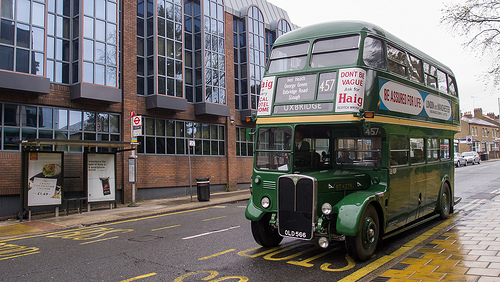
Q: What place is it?
A: It is a street.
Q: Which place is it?
A: It is a street.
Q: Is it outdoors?
A: Yes, it is outdoors.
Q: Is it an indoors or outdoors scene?
A: It is outdoors.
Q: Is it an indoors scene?
A: No, it is outdoors.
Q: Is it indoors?
A: No, it is outdoors.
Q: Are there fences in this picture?
A: No, there are no fences.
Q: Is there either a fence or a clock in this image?
A: No, there are no fences or clocks.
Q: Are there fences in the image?
A: No, there are no fences.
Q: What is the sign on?
A: The sign is on the pole.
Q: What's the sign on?
A: The sign is on the pole.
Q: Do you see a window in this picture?
A: Yes, there is a window.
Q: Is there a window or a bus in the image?
A: Yes, there is a window.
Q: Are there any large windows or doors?
A: Yes, there is a large window.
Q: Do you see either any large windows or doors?
A: Yes, there is a large window.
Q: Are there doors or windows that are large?
A: Yes, the window is large.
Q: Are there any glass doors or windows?
A: Yes, there is a glass window.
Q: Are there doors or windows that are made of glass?
A: Yes, the window is made of glass.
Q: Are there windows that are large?
A: Yes, there is a large window.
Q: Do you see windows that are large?
A: Yes, there is a window that is large.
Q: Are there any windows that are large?
A: Yes, there is a window that is large.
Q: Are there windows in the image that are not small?
A: Yes, there is a large window.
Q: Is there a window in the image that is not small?
A: Yes, there is a large window.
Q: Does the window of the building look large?
A: Yes, the window is large.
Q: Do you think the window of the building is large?
A: Yes, the window is large.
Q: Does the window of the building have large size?
A: Yes, the window is large.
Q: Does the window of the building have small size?
A: No, the window is large.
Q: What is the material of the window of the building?
A: The window is made of glass.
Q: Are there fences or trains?
A: No, there are no fences or trains.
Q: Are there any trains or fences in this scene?
A: No, there are no fences or trains.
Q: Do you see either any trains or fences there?
A: No, there are no fences or trains.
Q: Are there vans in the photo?
A: No, there are no vans.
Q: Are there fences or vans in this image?
A: No, there are no vans or fences.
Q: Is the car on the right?
A: Yes, the car is on the right of the image.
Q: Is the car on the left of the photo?
A: No, the car is on the right of the image.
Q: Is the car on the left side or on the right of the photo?
A: The car is on the right of the image.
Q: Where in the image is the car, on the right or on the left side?
A: The car is on the right of the image.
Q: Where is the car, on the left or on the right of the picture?
A: The car is on the right of the image.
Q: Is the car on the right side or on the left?
A: The car is on the right of the image.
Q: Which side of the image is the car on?
A: The car is on the right of the image.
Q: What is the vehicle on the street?
A: The vehicle is a car.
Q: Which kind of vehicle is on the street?
A: The vehicle is a car.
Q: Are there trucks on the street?
A: No, there is a car on the street.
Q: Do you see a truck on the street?
A: No, there is a car on the street.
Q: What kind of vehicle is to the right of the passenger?
A: The vehicle is a car.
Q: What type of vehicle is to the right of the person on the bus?
A: The vehicle is a car.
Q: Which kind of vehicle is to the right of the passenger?
A: The vehicle is a car.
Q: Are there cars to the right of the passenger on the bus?
A: Yes, there is a car to the right of the passenger.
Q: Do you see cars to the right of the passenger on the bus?
A: Yes, there is a car to the right of the passenger.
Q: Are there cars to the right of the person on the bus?
A: Yes, there is a car to the right of the passenger.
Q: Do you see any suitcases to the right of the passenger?
A: No, there is a car to the right of the passenger.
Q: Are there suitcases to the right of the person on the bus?
A: No, there is a car to the right of the passenger.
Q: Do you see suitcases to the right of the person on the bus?
A: No, there is a car to the right of the passenger.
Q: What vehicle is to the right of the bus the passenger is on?
A: The vehicle is a car.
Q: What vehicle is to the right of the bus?
A: The vehicle is a car.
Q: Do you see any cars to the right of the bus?
A: Yes, there is a car to the right of the bus.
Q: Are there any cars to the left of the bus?
A: No, the car is to the right of the bus.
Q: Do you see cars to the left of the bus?
A: No, the car is to the right of the bus.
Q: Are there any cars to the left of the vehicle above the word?
A: No, the car is to the right of the bus.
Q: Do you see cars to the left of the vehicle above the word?
A: No, the car is to the right of the bus.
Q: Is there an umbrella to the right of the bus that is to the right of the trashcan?
A: No, there is a car to the right of the bus.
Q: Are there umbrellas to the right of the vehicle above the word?
A: No, there is a car to the right of the bus.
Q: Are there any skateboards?
A: No, there are no skateboards.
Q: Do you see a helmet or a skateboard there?
A: No, there are no skateboards or helmets.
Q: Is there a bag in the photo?
A: No, there are no bags.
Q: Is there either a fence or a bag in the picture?
A: No, there are no bags or fences.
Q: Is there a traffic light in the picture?
A: No, there are no traffic lights.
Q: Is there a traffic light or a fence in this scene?
A: No, there are no traffic lights or fences.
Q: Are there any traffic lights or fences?
A: No, there are no traffic lights or fences.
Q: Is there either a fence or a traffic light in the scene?
A: No, there are no traffic lights or fences.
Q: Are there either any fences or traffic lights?
A: No, there are no traffic lights or fences.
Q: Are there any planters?
A: No, there are no planters.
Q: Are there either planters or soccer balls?
A: No, there are no planters or soccer balls.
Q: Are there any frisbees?
A: No, there are no frisbees.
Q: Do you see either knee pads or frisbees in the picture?
A: No, there are no frisbees or knee pads.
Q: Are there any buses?
A: Yes, there is a bus.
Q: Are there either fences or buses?
A: Yes, there is a bus.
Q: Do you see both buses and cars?
A: Yes, there are both a bus and a car.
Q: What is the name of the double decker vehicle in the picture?
A: The vehicle is a bus.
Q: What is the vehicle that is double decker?
A: The vehicle is a bus.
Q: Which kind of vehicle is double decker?
A: The vehicle is a bus.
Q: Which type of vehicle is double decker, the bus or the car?
A: The bus is double decker.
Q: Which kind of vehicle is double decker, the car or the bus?
A: The bus is double decker.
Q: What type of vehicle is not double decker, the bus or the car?
A: The car is not double decker.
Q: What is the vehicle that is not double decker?
A: The vehicle is a car.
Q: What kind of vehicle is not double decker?
A: The vehicle is a car.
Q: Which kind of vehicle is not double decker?
A: The vehicle is a car.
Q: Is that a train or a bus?
A: That is a bus.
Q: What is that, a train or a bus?
A: That is a bus.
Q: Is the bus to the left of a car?
A: Yes, the bus is to the left of a car.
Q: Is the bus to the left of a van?
A: No, the bus is to the left of a car.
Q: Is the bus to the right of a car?
A: No, the bus is to the left of a car.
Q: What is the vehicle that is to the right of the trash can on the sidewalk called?
A: The vehicle is a bus.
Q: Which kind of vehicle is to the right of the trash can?
A: The vehicle is a bus.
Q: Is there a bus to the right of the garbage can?
A: Yes, there is a bus to the right of the garbage can.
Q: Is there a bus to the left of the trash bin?
A: No, the bus is to the right of the trash bin.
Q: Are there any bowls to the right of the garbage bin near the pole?
A: No, there is a bus to the right of the trash bin.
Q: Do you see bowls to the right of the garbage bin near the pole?
A: No, there is a bus to the right of the trash bin.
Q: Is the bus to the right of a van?
A: No, the bus is to the right of the garbage can.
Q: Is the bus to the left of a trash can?
A: No, the bus is to the right of a trash can.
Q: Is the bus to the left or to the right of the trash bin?
A: The bus is to the right of the trash bin.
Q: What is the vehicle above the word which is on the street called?
A: The vehicle is a bus.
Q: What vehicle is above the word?
A: The vehicle is a bus.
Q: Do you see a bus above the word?
A: Yes, there is a bus above the word.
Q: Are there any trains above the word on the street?
A: No, there is a bus above the word.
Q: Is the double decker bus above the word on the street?
A: Yes, the bus is above the word.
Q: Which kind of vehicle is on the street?
A: The vehicle is a bus.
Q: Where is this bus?
A: The bus is on the street.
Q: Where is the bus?
A: The bus is on the street.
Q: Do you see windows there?
A: Yes, there is a window.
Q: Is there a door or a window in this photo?
A: Yes, there is a window.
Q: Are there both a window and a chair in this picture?
A: No, there is a window but no chairs.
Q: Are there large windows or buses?
A: Yes, there is a large window.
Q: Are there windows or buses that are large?
A: Yes, the window is large.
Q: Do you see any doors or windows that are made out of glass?
A: Yes, the window is made of glass.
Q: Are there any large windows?
A: Yes, there is a large window.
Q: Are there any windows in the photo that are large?
A: Yes, there is a window that is large.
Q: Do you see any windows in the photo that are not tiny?
A: Yes, there is a large window.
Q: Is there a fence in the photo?
A: No, there are no fences.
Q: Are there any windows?
A: Yes, there is a window.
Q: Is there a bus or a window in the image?
A: Yes, there is a window.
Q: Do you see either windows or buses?
A: Yes, there is a window.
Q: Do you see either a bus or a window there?
A: Yes, there is a window.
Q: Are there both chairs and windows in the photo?
A: No, there is a window but no chairs.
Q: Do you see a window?
A: Yes, there is a window.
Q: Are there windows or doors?
A: Yes, there is a window.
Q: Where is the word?
A: The word is on the street.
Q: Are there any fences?
A: No, there are no fences.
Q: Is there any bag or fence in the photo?
A: No, there are no fences or bags.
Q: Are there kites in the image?
A: No, there are no kites.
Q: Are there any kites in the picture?
A: No, there are no kites.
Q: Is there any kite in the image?
A: No, there are no kites.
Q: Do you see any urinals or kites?
A: No, there are no kites or urinals.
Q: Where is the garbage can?
A: The garbage can is on the sidewalk.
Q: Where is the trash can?
A: The garbage can is on the sidewalk.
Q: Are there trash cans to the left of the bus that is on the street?
A: Yes, there is a trash can to the left of the bus.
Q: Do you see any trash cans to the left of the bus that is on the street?
A: Yes, there is a trash can to the left of the bus.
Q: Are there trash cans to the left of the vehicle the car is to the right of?
A: Yes, there is a trash can to the left of the bus.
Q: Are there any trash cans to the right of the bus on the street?
A: No, the trash can is to the left of the bus.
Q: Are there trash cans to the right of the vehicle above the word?
A: No, the trash can is to the left of the bus.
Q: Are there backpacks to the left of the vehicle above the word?
A: No, there is a trash can to the left of the bus.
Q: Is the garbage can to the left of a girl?
A: No, the garbage can is to the left of the bus.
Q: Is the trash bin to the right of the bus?
A: No, the trash bin is to the left of the bus.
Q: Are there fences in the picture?
A: No, there are no fences.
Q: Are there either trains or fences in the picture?
A: No, there are no fences or trains.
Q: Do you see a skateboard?
A: No, there are no skateboards.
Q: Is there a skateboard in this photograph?
A: No, there are no skateboards.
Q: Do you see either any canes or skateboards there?
A: No, there are no skateboards or canes.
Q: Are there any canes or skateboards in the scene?
A: No, there are no skateboards or canes.